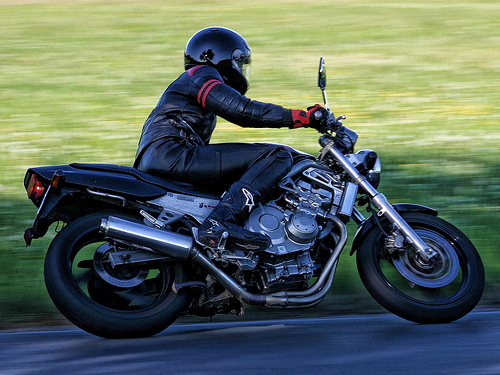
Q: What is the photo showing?
A: It is showing a field.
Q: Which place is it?
A: It is a field.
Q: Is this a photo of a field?
A: Yes, it is showing a field.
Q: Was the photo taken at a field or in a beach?
A: It was taken at a field.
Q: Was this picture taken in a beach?
A: No, the picture was taken in a field.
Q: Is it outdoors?
A: Yes, it is outdoors.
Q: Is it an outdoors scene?
A: Yes, it is outdoors.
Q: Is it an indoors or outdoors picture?
A: It is outdoors.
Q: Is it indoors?
A: No, it is outdoors.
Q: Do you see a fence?
A: No, there are no fences.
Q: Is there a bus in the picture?
A: No, there are no buses.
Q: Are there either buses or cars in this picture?
A: No, there are no buses or cars.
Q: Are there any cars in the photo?
A: No, there are no cars.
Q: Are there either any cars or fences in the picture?
A: No, there are no cars or fences.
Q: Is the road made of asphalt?
A: Yes, the road is made of asphalt.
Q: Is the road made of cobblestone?
A: No, the road is made of asphalt.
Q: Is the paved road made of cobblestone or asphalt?
A: The road is made of asphalt.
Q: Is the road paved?
A: Yes, the road is paved.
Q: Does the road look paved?
A: Yes, the road is paved.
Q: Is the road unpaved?
A: No, the road is paved.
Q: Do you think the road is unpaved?
A: No, the road is paved.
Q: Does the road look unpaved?
A: No, the road is paved.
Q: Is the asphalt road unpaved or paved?
A: The road is paved.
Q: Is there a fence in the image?
A: No, there are no fences.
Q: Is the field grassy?
A: Yes, the field is grassy.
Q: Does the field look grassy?
A: Yes, the field is grassy.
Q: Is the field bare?
A: No, the field is grassy.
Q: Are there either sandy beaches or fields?
A: No, there is a field but it is grassy.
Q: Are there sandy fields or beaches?
A: No, there is a field but it is grassy.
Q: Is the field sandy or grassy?
A: The field is grassy.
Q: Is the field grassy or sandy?
A: The field is grassy.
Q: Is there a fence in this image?
A: No, there are no fences.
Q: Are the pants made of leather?
A: Yes, the pants are made of leather.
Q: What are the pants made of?
A: The trousers are made of leather.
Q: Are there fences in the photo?
A: No, there are no fences.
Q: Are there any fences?
A: No, there are no fences.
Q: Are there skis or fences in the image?
A: No, there are no fences or skis.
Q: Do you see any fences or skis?
A: No, there are no fences or skis.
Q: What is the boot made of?
A: The boot is made of leather.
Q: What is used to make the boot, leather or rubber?
A: The boot is made of leather.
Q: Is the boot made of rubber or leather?
A: The boot is made of leather.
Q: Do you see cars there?
A: No, there are no cars.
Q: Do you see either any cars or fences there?
A: No, there are no cars or fences.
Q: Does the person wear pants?
A: Yes, the person wears pants.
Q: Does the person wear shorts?
A: No, the person wears pants.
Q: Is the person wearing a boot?
A: Yes, the person is wearing a boot.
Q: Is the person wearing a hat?
A: No, the person is wearing a boot.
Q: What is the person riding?
A: The person is riding a motorcycle.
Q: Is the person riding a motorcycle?
A: Yes, the person is riding a motorcycle.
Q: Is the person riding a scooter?
A: No, the person is riding a motorcycle.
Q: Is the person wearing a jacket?
A: Yes, the person is wearing a jacket.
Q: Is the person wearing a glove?
A: Yes, the person is wearing a glove.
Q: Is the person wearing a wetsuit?
A: No, the person is wearing a glove.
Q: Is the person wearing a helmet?
A: Yes, the person is wearing a helmet.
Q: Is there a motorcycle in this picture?
A: Yes, there is a motorcycle.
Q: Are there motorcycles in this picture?
A: Yes, there is a motorcycle.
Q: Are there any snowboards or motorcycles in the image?
A: Yes, there is a motorcycle.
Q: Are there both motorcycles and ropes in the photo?
A: No, there is a motorcycle but no ropes.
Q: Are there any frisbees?
A: No, there are no frisbees.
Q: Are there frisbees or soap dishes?
A: No, there are no frisbees or soap dishes.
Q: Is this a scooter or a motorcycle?
A: This is a motorcycle.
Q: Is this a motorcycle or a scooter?
A: This is a motorcycle.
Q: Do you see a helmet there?
A: Yes, there is a helmet.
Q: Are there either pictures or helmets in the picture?
A: Yes, there is a helmet.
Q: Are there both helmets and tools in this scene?
A: No, there is a helmet but no tools.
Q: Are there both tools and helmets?
A: No, there is a helmet but no tools.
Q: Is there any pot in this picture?
A: No, there are no pots.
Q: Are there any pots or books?
A: No, there are no pots or books.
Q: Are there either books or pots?
A: No, there are no pots or books.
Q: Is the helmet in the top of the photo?
A: Yes, the helmet is in the top of the image.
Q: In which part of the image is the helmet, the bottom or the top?
A: The helmet is in the top of the image.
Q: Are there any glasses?
A: No, there are no glasses.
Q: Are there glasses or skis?
A: No, there are no glasses or skis.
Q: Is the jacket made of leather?
A: Yes, the jacket is made of leather.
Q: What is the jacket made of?
A: The jacket is made of leather.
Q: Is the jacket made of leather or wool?
A: The jacket is made of leather.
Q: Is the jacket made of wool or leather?
A: The jacket is made of leather.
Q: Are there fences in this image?
A: No, there are no fences.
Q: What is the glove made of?
A: The glove is made of leather.